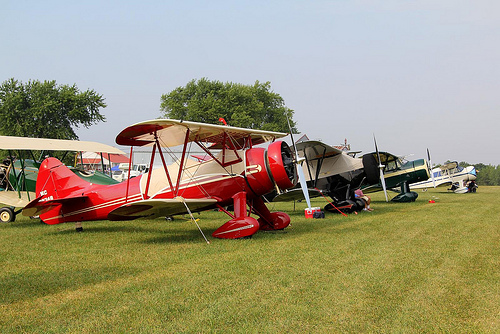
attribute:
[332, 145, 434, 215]
plane — blue, tan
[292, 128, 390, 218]
plane — black, white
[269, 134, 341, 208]
propeller — metal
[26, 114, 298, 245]
plane — red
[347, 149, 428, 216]
airplane — green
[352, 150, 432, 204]
airplane — green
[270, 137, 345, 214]
propeller — silver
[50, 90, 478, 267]
planes — five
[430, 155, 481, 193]
airplane — white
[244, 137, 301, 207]
propeller — red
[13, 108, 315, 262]
planes — bi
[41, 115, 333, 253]
airplane — blue, white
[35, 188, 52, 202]
writing — white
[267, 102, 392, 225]
plane — tan, beige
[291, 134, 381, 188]
plane — white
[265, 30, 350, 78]
blue sky — clear, weather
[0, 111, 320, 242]
plane — red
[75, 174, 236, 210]
stripes — white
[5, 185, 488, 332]
grass — brown, green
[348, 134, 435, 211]
plane — green, yellow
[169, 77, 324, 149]
tree — green, leafy, in back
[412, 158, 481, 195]
white plane — blue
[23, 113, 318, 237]
plane — orange, beige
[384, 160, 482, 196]
plane — white, blue